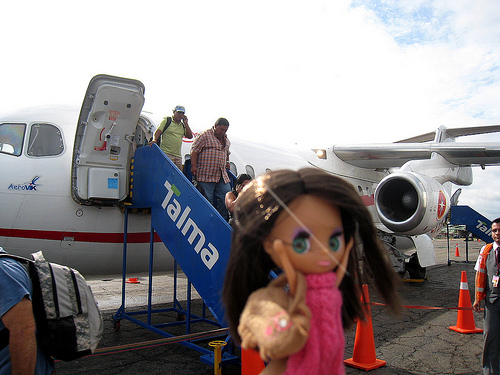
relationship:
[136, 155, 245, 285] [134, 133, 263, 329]
talma logo on stairs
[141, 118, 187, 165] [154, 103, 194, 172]
backpack on man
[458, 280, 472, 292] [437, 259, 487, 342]
stripe on orange cone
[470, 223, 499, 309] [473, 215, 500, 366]
orange vest on an airport employee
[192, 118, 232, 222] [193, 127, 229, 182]
man wearing checkered shirt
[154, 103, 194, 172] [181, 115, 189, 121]
man talking on on a cell phone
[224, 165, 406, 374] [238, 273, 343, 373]
childs wearing clothes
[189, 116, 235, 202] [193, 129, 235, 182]
man wearing checkered shirt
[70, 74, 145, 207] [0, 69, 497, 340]
an open door on airplane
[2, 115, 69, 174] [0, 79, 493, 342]
windows of plane on plane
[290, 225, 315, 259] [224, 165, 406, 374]
eye of the toy doll on childs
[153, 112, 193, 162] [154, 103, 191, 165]
green shirt on man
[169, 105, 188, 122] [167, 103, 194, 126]
white hat on head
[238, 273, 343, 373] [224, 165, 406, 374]
clothes on childs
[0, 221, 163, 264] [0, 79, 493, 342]
red stripe on plane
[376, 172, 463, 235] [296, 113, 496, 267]
engine on plane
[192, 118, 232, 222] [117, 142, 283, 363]
man walking down airplane ladder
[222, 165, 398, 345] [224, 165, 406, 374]
dolls hair on childs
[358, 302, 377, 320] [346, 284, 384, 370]
stripe on orange safety cone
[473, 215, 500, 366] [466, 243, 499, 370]
an airport employee wearing airport uniform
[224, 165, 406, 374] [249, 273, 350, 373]
childs wearing dress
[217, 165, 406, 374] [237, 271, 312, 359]
childs wearing cloth doll purse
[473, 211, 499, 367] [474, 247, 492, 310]
an airport employee wearing orange vest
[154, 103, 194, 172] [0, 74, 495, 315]
man getting off airplane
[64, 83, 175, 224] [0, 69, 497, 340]
an open door on airplane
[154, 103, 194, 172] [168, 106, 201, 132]
man on on a cell phone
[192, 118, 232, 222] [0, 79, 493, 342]
man are departing plane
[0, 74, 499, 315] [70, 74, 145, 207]
airplane has an open door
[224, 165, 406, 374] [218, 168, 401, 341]
childs has hair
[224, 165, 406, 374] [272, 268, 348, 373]
childs has clothes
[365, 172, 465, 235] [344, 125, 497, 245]
engine under wing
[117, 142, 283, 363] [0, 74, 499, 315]
airplane ladder are leading airplane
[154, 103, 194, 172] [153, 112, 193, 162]
man wearing green shirt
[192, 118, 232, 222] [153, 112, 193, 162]
man wearing green shirt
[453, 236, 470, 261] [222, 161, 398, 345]
safety cone behind behind dolls hair